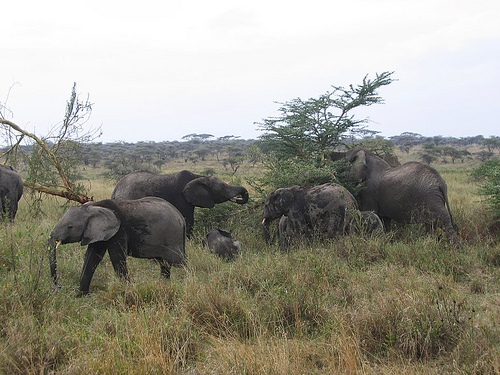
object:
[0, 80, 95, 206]
tree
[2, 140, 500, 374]
ground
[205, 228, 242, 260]
elephant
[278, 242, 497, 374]
vegetation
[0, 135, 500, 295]
area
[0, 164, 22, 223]
elephants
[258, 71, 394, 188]
green foliage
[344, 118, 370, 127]
tree branch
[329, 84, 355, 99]
tree branch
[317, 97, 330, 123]
tree branch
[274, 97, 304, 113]
tree branch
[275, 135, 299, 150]
tree branch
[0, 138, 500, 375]
plain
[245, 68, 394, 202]
tree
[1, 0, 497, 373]
photo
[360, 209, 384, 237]
elephants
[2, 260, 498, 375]
tall grass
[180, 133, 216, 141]
trees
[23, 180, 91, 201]
tree trunk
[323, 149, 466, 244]
elephant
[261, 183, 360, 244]
elephant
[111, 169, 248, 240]
elephant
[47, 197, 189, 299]
elephant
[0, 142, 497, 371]
field